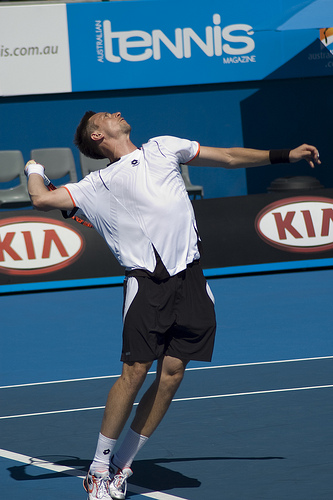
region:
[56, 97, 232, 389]
man playing tennis on tennis court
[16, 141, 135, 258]
man with tennis rack behind his back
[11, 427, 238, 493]
mans shadow on ground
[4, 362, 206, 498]
white lines on tennis court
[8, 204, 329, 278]
black barrier with red and white kia ad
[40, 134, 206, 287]
man with white shirt on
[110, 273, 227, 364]
man in black and white shorts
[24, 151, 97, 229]
red and black tennis racket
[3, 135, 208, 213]
empty grey chairs in background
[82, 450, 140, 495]
red and white shoe laces on mans shoes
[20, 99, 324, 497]
A tennis player swinging a racket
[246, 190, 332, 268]
A large red and white KIA sign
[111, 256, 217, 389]
Black and white knee-length shorts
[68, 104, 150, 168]
A man with an intense look on his face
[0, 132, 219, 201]
Empty grey seats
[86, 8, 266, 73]
An Australian Tennis Magazine sign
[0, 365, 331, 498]
A clean tennis court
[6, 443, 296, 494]
A man's shadow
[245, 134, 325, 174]
A black armband on a man's wrist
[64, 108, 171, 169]
A man looking upwards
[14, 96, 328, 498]
a tennis player trying to hit a ball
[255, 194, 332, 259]
logotype on side of board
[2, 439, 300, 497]
s shadow on tennis curt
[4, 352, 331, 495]
white lines on tennis curt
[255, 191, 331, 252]
a logo with red letters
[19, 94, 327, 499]
tennis player is looking up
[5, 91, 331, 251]
man has left arm extended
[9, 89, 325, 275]
tennis player has a racket in his right arm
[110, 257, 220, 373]
black short with white stripes on sides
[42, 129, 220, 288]
tee shirt is white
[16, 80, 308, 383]
a man playing tennis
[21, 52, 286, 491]
a man playing tennis on a court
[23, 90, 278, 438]
a man playing tennis outside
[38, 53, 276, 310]
a man leaning back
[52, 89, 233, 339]
a man wearing a tennis outfit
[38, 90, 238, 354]
a man wearing shorts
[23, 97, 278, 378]
a tennis player wearing shorts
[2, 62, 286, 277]
a tennis player leaning back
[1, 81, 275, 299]
a tennis player during the day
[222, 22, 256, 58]
large white letter on blue background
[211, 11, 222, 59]
large white letter on blue background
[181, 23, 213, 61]
large white letter on blue background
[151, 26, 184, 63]
large white letter on blue background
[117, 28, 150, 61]
large white letter on blue background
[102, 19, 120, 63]
large white letter on blue background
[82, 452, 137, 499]
pair of white shoes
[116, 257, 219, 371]
pair of black shorts with white accents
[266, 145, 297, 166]
black wristband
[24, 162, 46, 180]
white wristband